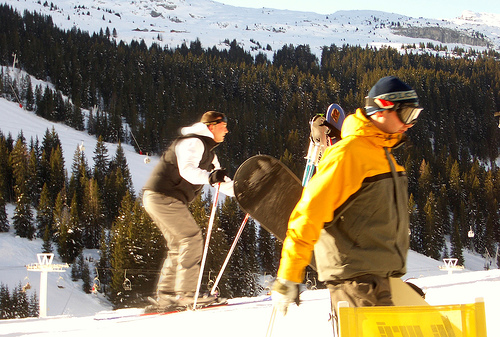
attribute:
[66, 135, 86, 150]
snow — white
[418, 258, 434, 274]
snow — fresh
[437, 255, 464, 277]
cross — white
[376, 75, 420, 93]
cap — brown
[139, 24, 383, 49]
mountain — snow covered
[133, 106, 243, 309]
skier — crouching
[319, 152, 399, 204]
ski jacket — yellow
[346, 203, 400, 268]
jacket — gray, yellow, grey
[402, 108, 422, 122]
goggles — black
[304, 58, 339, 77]
trees — evergreen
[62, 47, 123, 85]
forest — pine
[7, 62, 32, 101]
ski lift — white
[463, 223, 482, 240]
cable — strong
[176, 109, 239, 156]
man — moving uphill, sking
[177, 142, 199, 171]
sweatshirt — white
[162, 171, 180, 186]
vest — black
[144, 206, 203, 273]
pants — khaki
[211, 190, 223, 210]
ski poles — red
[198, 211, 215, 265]
poles — white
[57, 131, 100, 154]
slope — snow covered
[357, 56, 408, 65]
fir trees — green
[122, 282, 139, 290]
lift — strong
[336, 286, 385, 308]
pants — gray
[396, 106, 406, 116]
googles — pair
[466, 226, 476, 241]
lift — white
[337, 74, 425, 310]
man — snowboarding